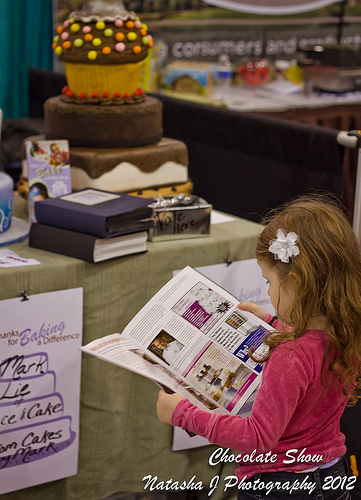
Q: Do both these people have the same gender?
A: No, they are both male and female.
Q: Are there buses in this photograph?
A: No, there are no buses.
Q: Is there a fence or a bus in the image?
A: No, there are no buses or fences.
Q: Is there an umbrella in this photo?
A: No, there are no umbrellas.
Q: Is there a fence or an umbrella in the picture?
A: No, there are no umbrellas or fences.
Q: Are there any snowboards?
A: No, there are no snowboards.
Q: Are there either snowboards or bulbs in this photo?
A: No, there are no snowboards or bulbs.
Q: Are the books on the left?
A: Yes, the books are on the left of the image.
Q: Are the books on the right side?
A: No, the books are on the left of the image.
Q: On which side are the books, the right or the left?
A: The books are on the left of the image.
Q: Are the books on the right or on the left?
A: The books are on the left of the image.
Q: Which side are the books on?
A: The books are on the left of the image.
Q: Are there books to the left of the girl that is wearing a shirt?
A: Yes, there are books to the left of the girl.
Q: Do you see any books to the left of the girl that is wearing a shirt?
A: Yes, there are books to the left of the girl.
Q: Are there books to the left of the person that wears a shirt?
A: Yes, there are books to the left of the girl.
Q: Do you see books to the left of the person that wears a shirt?
A: Yes, there are books to the left of the girl.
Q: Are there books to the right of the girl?
A: No, the books are to the left of the girl.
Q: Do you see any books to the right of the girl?
A: No, the books are to the left of the girl.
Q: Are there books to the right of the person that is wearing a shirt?
A: No, the books are to the left of the girl.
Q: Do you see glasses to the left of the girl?
A: No, there are books to the left of the girl.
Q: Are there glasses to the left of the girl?
A: No, there are books to the left of the girl.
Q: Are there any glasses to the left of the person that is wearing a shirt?
A: No, there are books to the left of the girl.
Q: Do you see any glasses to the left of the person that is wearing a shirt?
A: No, there are books to the left of the girl.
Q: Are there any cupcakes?
A: Yes, there is a cupcake.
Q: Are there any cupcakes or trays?
A: Yes, there is a cupcake.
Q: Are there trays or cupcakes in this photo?
A: Yes, there is a cupcake.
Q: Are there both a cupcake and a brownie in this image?
A: No, there is a cupcake but no brownies.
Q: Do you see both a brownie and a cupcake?
A: No, there is a cupcake but no brownies.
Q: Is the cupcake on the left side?
A: Yes, the cupcake is on the left of the image.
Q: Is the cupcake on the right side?
A: No, the cupcake is on the left of the image.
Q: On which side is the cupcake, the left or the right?
A: The cupcake is on the left of the image.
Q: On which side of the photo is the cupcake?
A: The cupcake is on the left of the image.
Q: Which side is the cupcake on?
A: The cupcake is on the left of the image.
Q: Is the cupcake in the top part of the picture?
A: Yes, the cupcake is in the top of the image.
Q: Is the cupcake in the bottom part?
A: No, the cupcake is in the top of the image.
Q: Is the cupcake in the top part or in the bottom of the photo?
A: The cupcake is in the top of the image.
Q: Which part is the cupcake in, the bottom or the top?
A: The cupcake is in the top of the image.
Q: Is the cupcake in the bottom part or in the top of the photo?
A: The cupcake is in the top of the image.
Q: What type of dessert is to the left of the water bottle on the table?
A: The dessert is a cupcake.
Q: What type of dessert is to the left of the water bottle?
A: The dessert is a cupcake.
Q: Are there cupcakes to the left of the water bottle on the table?
A: Yes, there is a cupcake to the left of the water bottle.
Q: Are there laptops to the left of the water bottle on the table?
A: No, there is a cupcake to the left of the water bottle.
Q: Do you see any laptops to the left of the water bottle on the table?
A: No, there is a cupcake to the left of the water bottle.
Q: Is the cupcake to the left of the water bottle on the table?
A: Yes, the cupcake is to the left of the water bottle.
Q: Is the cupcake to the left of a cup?
A: No, the cupcake is to the left of the water bottle.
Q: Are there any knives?
A: No, there are no knives.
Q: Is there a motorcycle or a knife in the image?
A: No, there are no knives or motorcycles.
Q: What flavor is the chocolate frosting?
A: This is a chocolate frosting.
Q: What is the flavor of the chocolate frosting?
A: This is a chocolate frosting.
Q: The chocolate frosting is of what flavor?
A: This is a chocolate frosting.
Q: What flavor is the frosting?
A: This is a chocolate frosting.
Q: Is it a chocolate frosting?
A: Yes, this is a chocolate frosting.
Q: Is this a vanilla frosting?
A: No, this is a chocolate frosting.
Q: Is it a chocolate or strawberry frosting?
A: This is a chocolate frosting.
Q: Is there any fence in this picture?
A: No, there are no fences.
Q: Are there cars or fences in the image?
A: No, there are no fences or cars.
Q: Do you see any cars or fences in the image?
A: No, there are no fences or cars.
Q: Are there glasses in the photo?
A: No, there are no glasses.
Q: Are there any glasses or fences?
A: No, there are no glasses or fences.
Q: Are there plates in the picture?
A: No, there are no plates.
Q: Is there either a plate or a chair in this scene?
A: No, there are no plates or chairs.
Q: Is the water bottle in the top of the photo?
A: Yes, the water bottle is in the top of the image.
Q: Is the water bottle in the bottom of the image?
A: No, the water bottle is in the top of the image.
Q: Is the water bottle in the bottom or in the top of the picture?
A: The water bottle is in the top of the image.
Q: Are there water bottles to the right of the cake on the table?
A: Yes, there is a water bottle to the right of the cake.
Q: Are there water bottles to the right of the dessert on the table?
A: Yes, there is a water bottle to the right of the cake.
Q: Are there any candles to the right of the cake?
A: No, there is a water bottle to the right of the cake.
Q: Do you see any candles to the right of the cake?
A: No, there is a water bottle to the right of the cake.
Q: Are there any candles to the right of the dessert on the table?
A: No, there is a water bottle to the right of the cake.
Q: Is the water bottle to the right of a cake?
A: Yes, the water bottle is to the right of a cake.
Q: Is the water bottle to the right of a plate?
A: No, the water bottle is to the right of a cake.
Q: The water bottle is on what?
A: The water bottle is on the table.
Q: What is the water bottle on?
A: The water bottle is on the table.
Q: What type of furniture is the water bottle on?
A: The water bottle is on the table.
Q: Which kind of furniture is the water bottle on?
A: The water bottle is on the table.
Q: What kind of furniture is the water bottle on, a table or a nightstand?
A: The water bottle is on a table.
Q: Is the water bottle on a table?
A: Yes, the water bottle is on a table.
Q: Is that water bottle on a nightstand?
A: No, the water bottle is on a table.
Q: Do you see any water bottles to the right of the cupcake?
A: Yes, there is a water bottle to the right of the cupcake.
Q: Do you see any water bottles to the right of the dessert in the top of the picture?
A: Yes, there is a water bottle to the right of the cupcake.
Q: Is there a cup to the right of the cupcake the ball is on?
A: No, there is a water bottle to the right of the cupcake.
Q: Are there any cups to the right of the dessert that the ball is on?
A: No, there is a water bottle to the right of the cupcake.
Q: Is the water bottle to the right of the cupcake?
A: Yes, the water bottle is to the right of the cupcake.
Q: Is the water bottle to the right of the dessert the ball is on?
A: Yes, the water bottle is to the right of the cupcake.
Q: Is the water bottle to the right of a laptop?
A: No, the water bottle is to the right of the cupcake.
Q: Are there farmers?
A: No, there are no farmers.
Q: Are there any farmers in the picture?
A: No, there are no farmers.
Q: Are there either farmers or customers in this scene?
A: No, there are no farmers or customers.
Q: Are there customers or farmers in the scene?
A: No, there are no farmers or customers.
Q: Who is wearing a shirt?
A: The girl is wearing a shirt.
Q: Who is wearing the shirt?
A: The girl is wearing a shirt.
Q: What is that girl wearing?
A: The girl is wearing a shirt.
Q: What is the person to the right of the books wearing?
A: The girl is wearing a shirt.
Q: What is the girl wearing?
A: The girl is wearing a shirt.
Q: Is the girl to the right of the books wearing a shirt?
A: Yes, the girl is wearing a shirt.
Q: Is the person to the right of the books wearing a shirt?
A: Yes, the girl is wearing a shirt.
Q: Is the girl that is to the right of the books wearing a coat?
A: No, the girl is wearing a shirt.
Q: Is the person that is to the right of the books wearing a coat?
A: No, the girl is wearing a shirt.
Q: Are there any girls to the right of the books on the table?
A: Yes, there is a girl to the right of the books.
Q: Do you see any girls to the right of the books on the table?
A: Yes, there is a girl to the right of the books.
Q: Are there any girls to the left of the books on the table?
A: No, the girl is to the right of the books.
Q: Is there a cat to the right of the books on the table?
A: No, there is a girl to the right of the books.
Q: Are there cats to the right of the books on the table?
A: No, there is a girl to the right of the books.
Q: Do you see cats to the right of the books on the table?
A: No, there is a girl to the right of the books.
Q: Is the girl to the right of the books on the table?
A: Yes, the girl is to the right of the books.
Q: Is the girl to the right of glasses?
A: No, the girl is to the right of the books.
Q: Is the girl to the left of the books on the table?
A: No, the girl is to the right of the books.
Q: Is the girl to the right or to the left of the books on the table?
A: The girl is to the right of the books.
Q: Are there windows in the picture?
A: Yes, there is a window.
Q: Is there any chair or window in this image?
A: Yes, there is a window.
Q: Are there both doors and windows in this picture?
A: No, there is a window but no doors.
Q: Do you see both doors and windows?
A: No, there is a window but no doors.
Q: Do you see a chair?
A: No, there are no chairs.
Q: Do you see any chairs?
A: No, there are no chairs.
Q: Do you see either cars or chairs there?
A: No, there are no chairs or cars.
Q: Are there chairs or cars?
A: No, there are no chairs or cars.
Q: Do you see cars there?
A: No, there are no cars.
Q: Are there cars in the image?
A: No, there are no cars.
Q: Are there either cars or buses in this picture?
A: No, there are no cars or buses.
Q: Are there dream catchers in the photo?
A: No, there are no dream catchers.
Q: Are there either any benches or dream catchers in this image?
A: No, there are no dream catchers or benches.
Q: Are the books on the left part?
A: Yes, the books are on the left of the image.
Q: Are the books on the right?
A: No, the books are on the left of the image.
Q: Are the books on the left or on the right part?
A: The books are on the left of the image.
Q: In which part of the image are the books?
A: The books are on the left of the image.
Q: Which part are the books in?
A: The books are on the left of the image.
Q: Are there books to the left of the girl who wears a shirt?
A: Yes, there are books to the left of the girl.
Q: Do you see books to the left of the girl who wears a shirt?
A: Yes, there are books to the left of the girl.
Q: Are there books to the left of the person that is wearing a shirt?
A: Yes, there are books to the left of the girl.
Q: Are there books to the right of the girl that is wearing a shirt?
A: No, the books are to the left of the girl.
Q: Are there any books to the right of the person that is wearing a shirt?
A: No, the books are to the left of the girl.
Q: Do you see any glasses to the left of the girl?
A: No, there are books to the left of the girl.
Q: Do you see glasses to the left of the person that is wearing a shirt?
A: No, there are books to the left of the girl.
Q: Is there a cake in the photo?
A: Yes, there is a cake.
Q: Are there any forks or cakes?
A: Yes, there is a cake.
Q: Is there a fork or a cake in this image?
A: Yes, there is a cake.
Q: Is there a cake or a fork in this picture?
A: Yes, there is a cake.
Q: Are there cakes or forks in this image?
A: Yes, there is a cake.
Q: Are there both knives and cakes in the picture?
A: No, there is a cake but no knives.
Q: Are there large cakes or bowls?
A: Yes, there is a large cake.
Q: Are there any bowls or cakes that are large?
A: Yes, the cake is large.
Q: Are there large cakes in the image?
A: Yes, there is a large cake.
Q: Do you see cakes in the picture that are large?
A: Yes, there is a cake that is large.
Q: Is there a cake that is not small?
A: Yes, there is a large cake.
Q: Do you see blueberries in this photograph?
A: No, there are no blueberries.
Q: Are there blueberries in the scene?
A: No, there are no blueberries.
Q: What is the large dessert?
A: The dessert is a cake.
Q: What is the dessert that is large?
A: The dessert is a cake.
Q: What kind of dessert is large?
A: The dessert is a cake.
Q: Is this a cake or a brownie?
A: This is a cake.